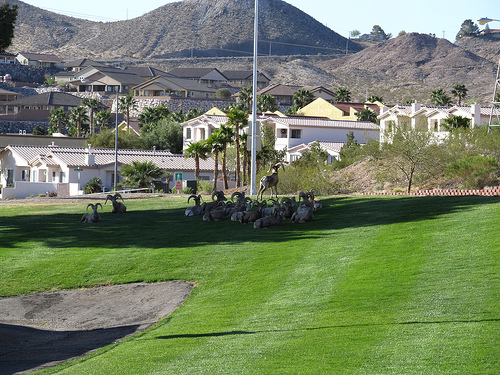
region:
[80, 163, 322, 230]
several mountain goats on a golf course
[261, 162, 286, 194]
one mountain goat standing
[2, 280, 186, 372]
a sand bunker on the golf course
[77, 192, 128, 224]
two goats to the left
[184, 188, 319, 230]
several goats laying in a huddle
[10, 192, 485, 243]
the shade of a tree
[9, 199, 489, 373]
green grass fairway of a golf course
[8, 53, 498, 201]
several houses on the hill above the golf course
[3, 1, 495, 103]
mountains beyond the houses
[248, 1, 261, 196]
a tall white pole by the standing goat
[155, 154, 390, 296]
animals in a field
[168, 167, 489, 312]
animals in a grass field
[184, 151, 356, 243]
animals in a green grass field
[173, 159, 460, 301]
animals with long horns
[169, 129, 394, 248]
long horned animals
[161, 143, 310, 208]
animals laying in a field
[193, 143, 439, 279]
animals laying in a grass field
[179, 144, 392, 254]
animals laying in a green grass field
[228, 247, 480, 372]
a green gras field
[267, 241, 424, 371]
a grass field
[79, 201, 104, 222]
a white ram sitting in the grass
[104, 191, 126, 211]
a white ram sitting in the grass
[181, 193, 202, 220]
a white ram sitting in the grass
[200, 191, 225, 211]
a white ram sitting in the grass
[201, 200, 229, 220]
a white ram sitting in the grass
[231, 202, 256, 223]
a white ram sitting in the grass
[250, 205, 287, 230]
a white ram sitting in the grass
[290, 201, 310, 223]
a white ram sitting in the grass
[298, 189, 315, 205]
a white ram sitting in the grass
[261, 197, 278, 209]
a white ram sitting in the grass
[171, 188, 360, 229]
animals sitting by the pole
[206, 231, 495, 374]
grass is neatly mowed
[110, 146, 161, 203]
palm bushes in the corner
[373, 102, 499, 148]
white house on the hill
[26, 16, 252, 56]
mountains in the distance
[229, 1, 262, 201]
pole in middle of grass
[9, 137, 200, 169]
roof is white on house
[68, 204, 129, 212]
horns of animal are large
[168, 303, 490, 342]
shadow from the sunlight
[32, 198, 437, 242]
animals in the shade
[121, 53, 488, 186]
a beautiful view of houses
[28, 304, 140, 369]
a shadow on the ground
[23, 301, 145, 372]
a shadow on the grass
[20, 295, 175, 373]
a shadow on the earth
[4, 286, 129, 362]
a shadow on the field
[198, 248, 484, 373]
a green view of grass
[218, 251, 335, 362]
a white line in the grass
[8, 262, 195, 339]
a road near the grass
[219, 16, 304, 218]
a long pole in road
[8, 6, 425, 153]
a beautiful view of mountain